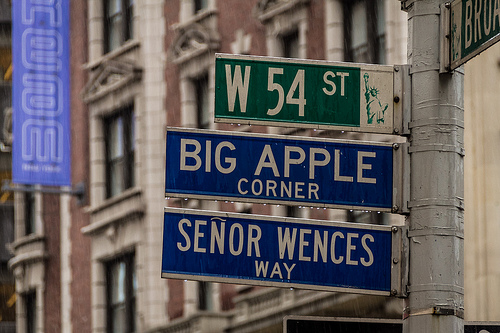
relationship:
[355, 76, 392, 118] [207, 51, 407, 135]
statue on sign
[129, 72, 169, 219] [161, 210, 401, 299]
post with street sign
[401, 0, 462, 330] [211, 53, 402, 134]
pole with street street sign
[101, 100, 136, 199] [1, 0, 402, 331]
window on building